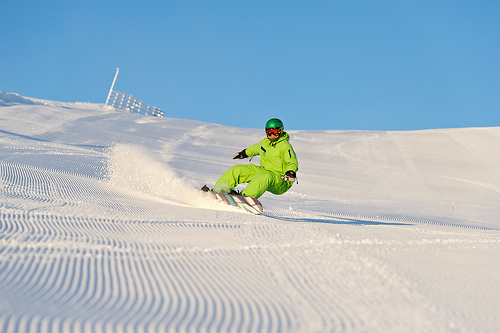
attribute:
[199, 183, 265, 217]
snowboard — colorful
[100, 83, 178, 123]
fence — white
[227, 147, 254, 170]
glove — nylon, black, white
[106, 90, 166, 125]
fence — white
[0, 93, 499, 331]
snow — fresh, mountain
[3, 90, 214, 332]
snow — white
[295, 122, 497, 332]
snow — white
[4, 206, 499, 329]
snow — white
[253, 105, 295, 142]
helmet — green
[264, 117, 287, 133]
helmet — dark green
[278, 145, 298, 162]
zipper — black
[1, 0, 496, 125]
sky — clear, blue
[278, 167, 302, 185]
glove — black, white, nylon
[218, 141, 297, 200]
snow suit — green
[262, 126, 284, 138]
goggles — dark red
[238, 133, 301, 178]
jacket — green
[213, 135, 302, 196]
snowsuit — neon green